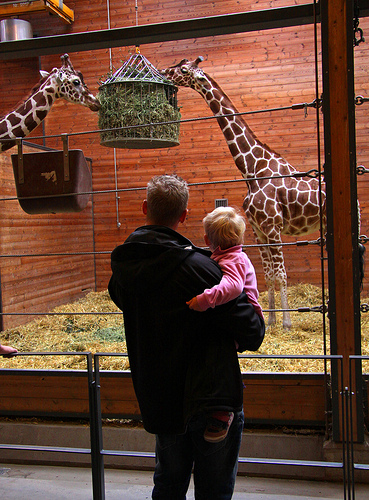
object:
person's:
[108, 172, 264, 499]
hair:
[144, 174, 189, 228]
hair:
[202, 204, 246, 250]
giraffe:
[0, 50, 100, 156]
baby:
[186, 206, 264, 321]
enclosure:
[2, 2, 368, 499]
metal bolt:
[285, 91, 330, 116]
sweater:
[195, 244, 265, 317]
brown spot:
[262, 149, 272, 161]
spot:
[204, 90, 214, 101]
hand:
[0, 344, 20, 359]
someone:
[107, 172, 266, 499]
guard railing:
[0, 1, 369, 431]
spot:
[228, 142, 239, 156]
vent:
[215, 198, 228, 207]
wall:
[0, 0, 367, 328]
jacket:
[107, 223, 263, 436]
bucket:
[10, 149, 93, 215]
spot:
[264, 165, 285, 187]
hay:
[95, 82, 181, 139]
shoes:
[204, 404, 235, 444]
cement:
[0, 425, 369, 500]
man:
[106, 174, 265, 498]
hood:
[109, 224, 191, 292]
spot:
[236, 131, 252, 154]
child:
[186, 206, 261, 443]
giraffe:
[156, 55, 361, 331]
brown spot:
[263, 186, 280, 203]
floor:
[1, 461, 368, 500]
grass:
[99, 81, 180, 144]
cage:
[97, 51, 182, 147]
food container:
[10, 149, 93, 215]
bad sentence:
[102, 121, 139, 178]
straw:
[0, 281, 369, 372]